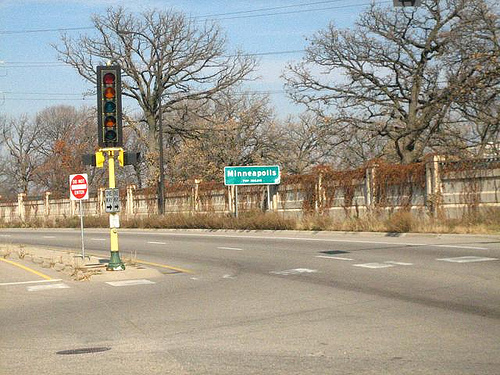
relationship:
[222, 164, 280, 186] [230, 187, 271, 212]
green sign on two poles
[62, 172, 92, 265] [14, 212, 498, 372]
sign on side of street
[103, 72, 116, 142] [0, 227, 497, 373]
lights on corner of road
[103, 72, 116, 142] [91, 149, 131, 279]
lights on pole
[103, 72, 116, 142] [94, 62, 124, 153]
lights at traffic signal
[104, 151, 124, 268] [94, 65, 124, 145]
pole at traffic signal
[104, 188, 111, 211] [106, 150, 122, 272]
sign on pole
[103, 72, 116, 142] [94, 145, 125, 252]
lights on pole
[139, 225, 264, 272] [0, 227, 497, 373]
lines on road